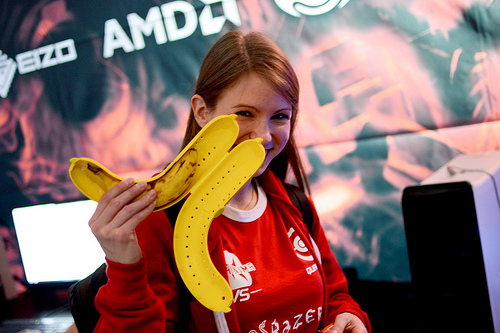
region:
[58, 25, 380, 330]
A woman holding a banana in a banana case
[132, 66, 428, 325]
a woman standing up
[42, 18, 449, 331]
a woman holding a banana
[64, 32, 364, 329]
a woman holding a banana holder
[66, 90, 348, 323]
a banana in a banana holder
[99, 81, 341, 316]
a banana in a yellow banana holder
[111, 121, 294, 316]
a yellow banana in banana holder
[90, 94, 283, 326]
banana in plastic banana holder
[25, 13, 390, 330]
a woman wearing a red shirt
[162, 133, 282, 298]
a woman wearing a red jacket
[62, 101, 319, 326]
a woman and banana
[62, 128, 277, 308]
yellow banana holder object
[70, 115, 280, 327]
plastic banana holder opened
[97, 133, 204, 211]
yellow banana being held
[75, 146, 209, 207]
yellow and brown banana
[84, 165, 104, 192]
yellow stem to banana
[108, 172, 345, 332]
red jacket on woman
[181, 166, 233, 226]
small holes on side of plastic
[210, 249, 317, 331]
white logos on front of shirt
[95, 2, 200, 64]
white writing on wall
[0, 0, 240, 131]
white logos on the wall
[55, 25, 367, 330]
A woman holding open a banana case with a banana inside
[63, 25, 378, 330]
A woman holding open a banana case with a banana inside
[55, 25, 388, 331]
A woman holding open a banana case with a banana inside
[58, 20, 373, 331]
A woman holding open a banana case with a banana inside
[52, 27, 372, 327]
A woman holding open a banana case with a banana inside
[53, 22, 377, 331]
A woman holding open a banana case with a banana inside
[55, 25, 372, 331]
A woman holding open a banana case with a banana inside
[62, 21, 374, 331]
A woman holding open a banana case with a banana inside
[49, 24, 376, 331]
A woman holding open a banana case with a banana inside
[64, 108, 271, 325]
a plastic yellow banana case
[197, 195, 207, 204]
a hole in a banana case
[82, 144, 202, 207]
a banana in a banana case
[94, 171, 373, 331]
a red jacket on a woman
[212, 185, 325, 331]
a red and white shirt on a woman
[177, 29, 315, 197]
light brown hair on a woman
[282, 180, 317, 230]
a black backpack strap on a woman's shoulder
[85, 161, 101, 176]
the blackened stem of a banana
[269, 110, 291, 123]
the eye of a woman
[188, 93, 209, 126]
an ear on a woman